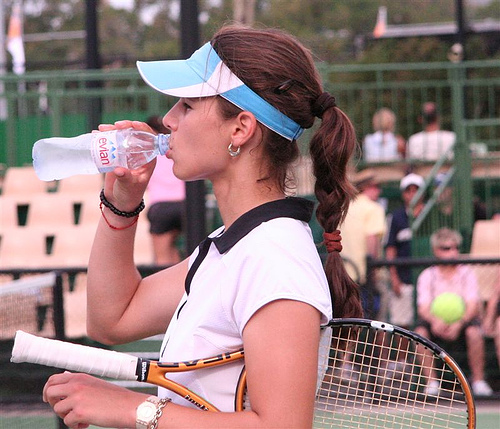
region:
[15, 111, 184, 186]
a bottle of water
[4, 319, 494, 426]
an orange tennis racket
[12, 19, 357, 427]
a tennis player drinking water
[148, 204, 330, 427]
a black and white shirt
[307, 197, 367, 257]
a red hair band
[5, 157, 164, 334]
a section of empty seating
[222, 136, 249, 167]
a silver earring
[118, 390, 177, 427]
a silver watch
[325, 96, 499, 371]
a group of spectators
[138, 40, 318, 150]
a blue and white visor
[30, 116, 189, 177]
a bottle of water quenching thirst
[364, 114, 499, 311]
spectaters in the stand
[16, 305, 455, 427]
a tennis racket under arm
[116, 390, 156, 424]
a watch that is fancy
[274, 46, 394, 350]
a long pony tail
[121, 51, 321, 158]
blue and white visor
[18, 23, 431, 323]
a tennis player drinks water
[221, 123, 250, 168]
round ear rings adorn her ears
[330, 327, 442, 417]
strings in the racket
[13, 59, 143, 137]
a green fence in the distance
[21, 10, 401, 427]
Woman is in the foreground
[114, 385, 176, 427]
Woman is wearing a wristwatch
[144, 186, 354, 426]
Woman is wearing a polo shirt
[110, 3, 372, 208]
A side view of a woman's head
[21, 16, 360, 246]
Woman is drinking bottled water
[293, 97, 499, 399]
A crowd of people in the background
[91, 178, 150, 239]
Woman is wearing a bracelet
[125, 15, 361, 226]
Woman is wearing a cap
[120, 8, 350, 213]
The cap is light blue and white in color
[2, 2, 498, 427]
Photo was taken in the daytime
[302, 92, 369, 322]
a brown ponytail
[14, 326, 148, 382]
the white handle of the racket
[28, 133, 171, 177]
a bottle of water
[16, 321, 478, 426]
a tennis racket under the girl's arm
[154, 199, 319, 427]
a black and white tennis uniform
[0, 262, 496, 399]
a black metal fence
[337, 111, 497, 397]
people sitting in the stands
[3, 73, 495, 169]
a green fence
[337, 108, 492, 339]
people in the background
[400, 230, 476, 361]
a lady sitting on a bench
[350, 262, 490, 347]
a black fence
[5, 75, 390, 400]
a tennis player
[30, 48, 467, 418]
a lady holding a tennis racket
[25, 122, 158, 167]
a water bottle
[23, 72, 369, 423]
a girl drinking a water bottle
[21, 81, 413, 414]
a girl wearing a visor